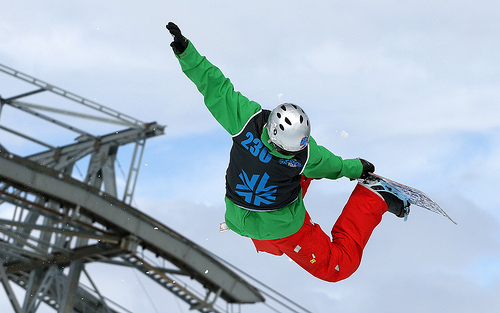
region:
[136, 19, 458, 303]
man doing trick in air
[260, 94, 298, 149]
silver helmet worn by man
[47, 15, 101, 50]
white clouds in blue sky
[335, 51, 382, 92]
white clouds in blue sky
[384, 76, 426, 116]
white clouds in blue sky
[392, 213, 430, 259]
white clouds in blue sky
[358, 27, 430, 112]
white clouds in blue sky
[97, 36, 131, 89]
white clouds in blue sky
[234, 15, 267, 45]
white clouds in blue sky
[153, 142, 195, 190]
white clouds in blue sky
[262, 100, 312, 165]
Head of athletic person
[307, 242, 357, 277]
Knee of athletic person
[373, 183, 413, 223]
Shoe of athletic person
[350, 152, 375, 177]
Hand of athletic person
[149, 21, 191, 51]
Hand of athletic person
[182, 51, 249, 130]
Arm of athletic person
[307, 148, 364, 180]
Arm of athletic person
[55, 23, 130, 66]
Cloudy sky above person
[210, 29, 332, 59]
Cloudy sky above person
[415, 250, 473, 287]
Cloudy sky above person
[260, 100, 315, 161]
Head of athletic skateboarder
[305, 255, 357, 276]
Knee of athletic skateboarder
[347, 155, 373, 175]
Hand of athletic skateboarder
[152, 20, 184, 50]
Hand of athletic skateboarder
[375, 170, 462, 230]
Part of athletic person's skateboard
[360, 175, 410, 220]
Foot of athletic skateboarder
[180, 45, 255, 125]
Arm of athletic skateboarder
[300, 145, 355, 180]
Arm of an athletic skateboarder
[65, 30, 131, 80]
Cloudy sky above a skateboarder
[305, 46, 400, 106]
Cloudy sky above a skateboarder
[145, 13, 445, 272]
snow boarder in the air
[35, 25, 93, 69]
white clouds in blue sky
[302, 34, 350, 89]
white clouds in blue sky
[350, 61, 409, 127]
white clouds in blue sky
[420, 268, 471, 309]
white clouds in blue sky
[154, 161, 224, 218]
white clouds in blue sky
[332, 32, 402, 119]
white clouds in blue sky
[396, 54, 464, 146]
white clouds in blue sky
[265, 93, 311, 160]
silver helmet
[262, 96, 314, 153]
a silver helmet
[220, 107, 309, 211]
a black vest with blue entry number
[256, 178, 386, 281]
red snow pants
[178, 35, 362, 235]
bright green jacket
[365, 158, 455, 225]
a snowboard with black boots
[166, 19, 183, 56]
a black glove on outstretched arm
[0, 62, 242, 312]
a grey metal structure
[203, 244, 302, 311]
cables are attached to the structure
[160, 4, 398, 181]
arms are out for balance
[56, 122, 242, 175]
piece of blue sky between clouds